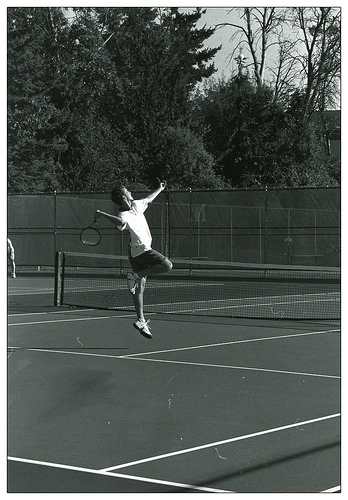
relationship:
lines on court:
[9, 291, 342, 316] [8, 263, 338, 491]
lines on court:
[123, 327, 339, 354] [8, 263, 338, 491]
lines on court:
[120, 355, 339, 380] [8, 263, 338, 491]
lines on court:
[71, 413, 340, 474] [8, 263, 338, 491]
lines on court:
[8, 455, 235, 492] [8, 263, 338, 491]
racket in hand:
[80, 215, 101, 246] [93, 208, 102, 219]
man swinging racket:
[83, 178, 203, 344] [51, 194, 118, 261]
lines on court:
[75, 308, 279, 499] [8, 263, 338, 491]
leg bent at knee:
[147, 239, 182, 275] [158, 253, 188, 287]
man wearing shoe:
[94, 183, 173, 339] [133, 318, 153, 338]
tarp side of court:
[203, 173, 312, 252] [39, 288, 294, 398]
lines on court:
[71, 318, 289, 493] [130, 308, 238, 418]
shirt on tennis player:
[115, 198, 152, 259] [93, 176, 177, 342]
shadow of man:
[5, 345, 128, 353] [94, 183, 173, 339]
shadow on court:
[5, 345, 128, 353] [8, 263, 338, 491]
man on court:
[94, 183, 173, 339] [8, 263, 338, 491]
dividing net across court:
[53, 249, 341, 324] [54, 83, 343, 345]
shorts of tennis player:
[128, 246, 167, 273] [111, 183, 172, 334]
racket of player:
[74, 213, 107, 251] [75, 173, 195, 345]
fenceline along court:
[8, 192, 338, 269] [15, 232, 347, 487]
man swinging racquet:
[94, 183, 173, 339] [79, 213, 101, 243]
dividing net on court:
[53, 249, 341, 324] [8, 263, 338, 491]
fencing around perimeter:
[185, 191, 343, 275] [7, 265, 339, 277]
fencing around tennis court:
[185, 191, 343, 275] [64, 304, 347, 478]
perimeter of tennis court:
[7, 265, 339, 277] [64, 304, 347, 478]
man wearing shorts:
[94, 183, 173, 339] [127, 249, 166, 272]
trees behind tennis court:
[6, 6, 340, 191] [7, 271, 341, 491]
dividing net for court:
[53, 249, 341, 324] [9, 260, 343, 489]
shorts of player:
[118, 246, 170, 270] [85, 170, 194, 339]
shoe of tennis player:
[133, 318, 153, 338] [93, 181, 172, 339]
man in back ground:
[94, 183, 173, 339] [41, 180, 343, 264]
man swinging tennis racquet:
[94, 183, 173, 339] [40, 199, 114, 252]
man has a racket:
[94, 183, 173, 339] [80, 215, 101, 246]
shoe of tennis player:
[126, 268, 140, 297] [93, 176, 177, 342]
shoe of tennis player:
[133, 315, 154, 338] [93, 176, 177, 342]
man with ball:
[94, 183, 173, 339] [159, 178, 170, 188]